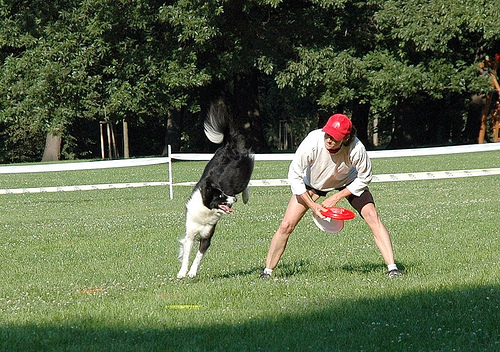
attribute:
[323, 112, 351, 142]
cap — red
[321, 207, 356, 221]
frisbee — plastic, red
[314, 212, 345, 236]
frisbee — white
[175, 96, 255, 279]
dog — excited, here, jumping, black, white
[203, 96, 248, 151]
tail — white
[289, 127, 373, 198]
shirt — long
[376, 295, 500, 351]
flower — white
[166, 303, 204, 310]
patch — yellow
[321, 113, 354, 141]
hat — red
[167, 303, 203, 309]
frisbee — yellow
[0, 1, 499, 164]
tree — green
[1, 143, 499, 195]
fence — white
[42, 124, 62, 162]
trunk — grey